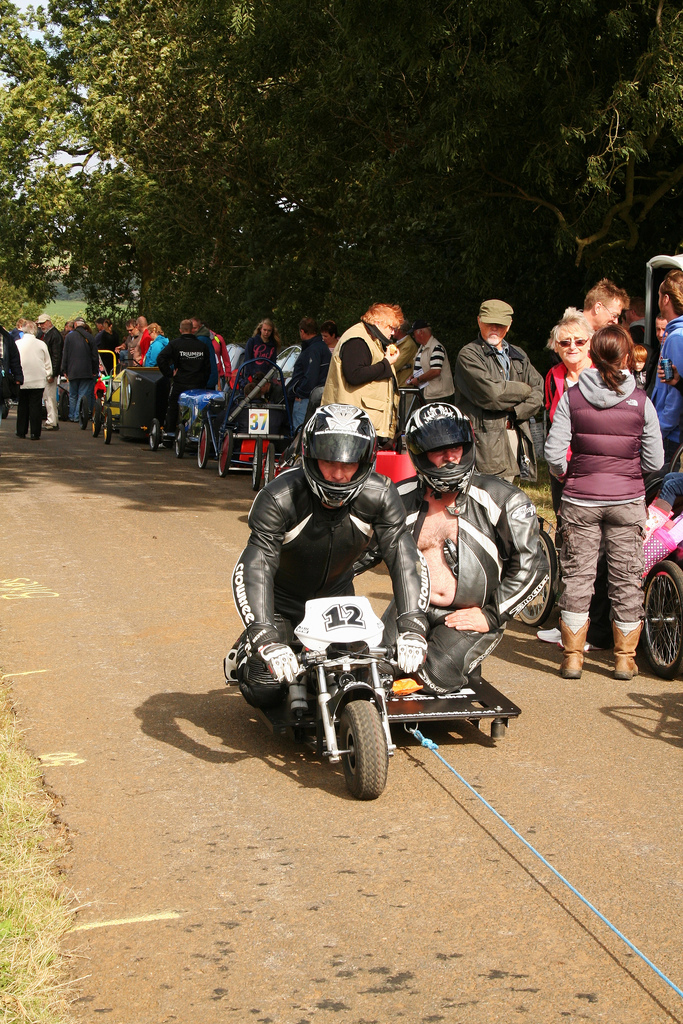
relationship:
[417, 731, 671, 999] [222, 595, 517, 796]
cord attached to bike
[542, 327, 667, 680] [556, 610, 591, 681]
woman wearing boots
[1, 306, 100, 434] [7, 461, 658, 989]
people on side of road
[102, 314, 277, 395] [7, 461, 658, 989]
people on side of road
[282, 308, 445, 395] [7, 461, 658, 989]
people on side of road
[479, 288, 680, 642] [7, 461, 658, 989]
people on side of road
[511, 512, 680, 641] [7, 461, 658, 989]
vehicle on side of road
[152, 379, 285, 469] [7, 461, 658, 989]
vehicles on side of road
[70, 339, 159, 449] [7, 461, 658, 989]
vehicles on side of road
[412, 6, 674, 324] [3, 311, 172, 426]
trees behind people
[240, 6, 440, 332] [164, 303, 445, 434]
trees behind people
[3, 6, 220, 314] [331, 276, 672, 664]
trees behind people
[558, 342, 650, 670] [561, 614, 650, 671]
woman wears boots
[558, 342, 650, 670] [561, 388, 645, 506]
woman wears vest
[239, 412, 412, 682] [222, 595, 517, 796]
man on bike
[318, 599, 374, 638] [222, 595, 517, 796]
12 number on bike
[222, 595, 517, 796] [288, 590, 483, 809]
bike has wheel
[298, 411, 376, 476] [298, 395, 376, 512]
helmet on head